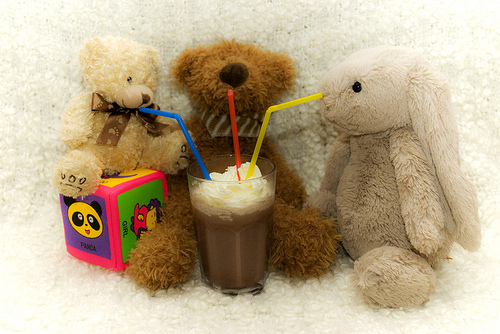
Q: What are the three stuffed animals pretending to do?
A: Drink.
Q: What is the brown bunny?
A: A stuffed animal.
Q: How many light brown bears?
A: One.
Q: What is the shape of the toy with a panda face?
A: A square block.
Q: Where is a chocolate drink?
A: In a glass.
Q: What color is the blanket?
A: White.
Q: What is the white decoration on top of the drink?
A: Whipped cream.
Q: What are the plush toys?
A: Stuffed animals.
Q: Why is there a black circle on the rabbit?
A: It's an eye.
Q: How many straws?
A: Three.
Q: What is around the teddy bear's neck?
A: A bowtie.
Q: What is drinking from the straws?
A: Stuffed animals.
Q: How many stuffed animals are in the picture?
A: 3.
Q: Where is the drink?
A: In a glass.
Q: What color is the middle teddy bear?
A: Brown.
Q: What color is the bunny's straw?
A: Yellow.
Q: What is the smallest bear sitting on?
A: A toy block.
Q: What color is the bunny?
A: White.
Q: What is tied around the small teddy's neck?
A: A ribbon.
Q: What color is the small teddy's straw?
A: Blue.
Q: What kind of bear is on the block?
A: Panda bear.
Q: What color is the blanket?
A: White.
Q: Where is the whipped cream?
A: In drink.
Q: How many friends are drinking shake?
A: Three.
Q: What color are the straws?
A: Red,Blue and Yellow.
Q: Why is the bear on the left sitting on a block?
A: It is smaller than the others.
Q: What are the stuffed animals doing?
A: Drinking a float.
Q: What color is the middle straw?
A: Red.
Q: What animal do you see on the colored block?
A: Panda.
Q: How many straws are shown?
A: Three.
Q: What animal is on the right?
A: Rabbit.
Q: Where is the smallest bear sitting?
A: On the left side.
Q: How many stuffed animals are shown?
A: Three.